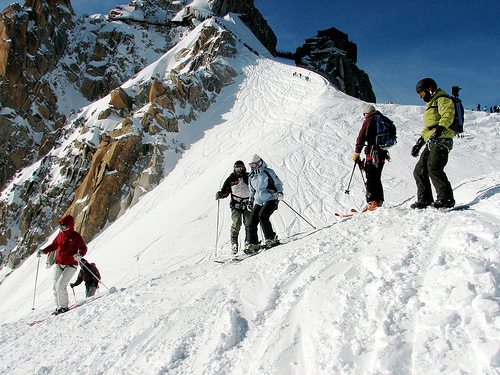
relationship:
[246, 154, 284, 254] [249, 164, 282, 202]
person wears jacket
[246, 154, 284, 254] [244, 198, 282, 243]
person wears pants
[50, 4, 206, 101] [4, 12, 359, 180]
snow on mountain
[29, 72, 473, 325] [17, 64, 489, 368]
people on hill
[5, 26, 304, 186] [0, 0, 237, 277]
snow on rocks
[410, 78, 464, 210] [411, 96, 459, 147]
man wears green jacket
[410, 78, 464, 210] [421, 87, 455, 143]
man wears green jacket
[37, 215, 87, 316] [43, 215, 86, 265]
people wears jacket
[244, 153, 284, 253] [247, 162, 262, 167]
person wears goggles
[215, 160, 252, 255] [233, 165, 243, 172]
man wears goggles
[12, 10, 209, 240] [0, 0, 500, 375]
snow on hill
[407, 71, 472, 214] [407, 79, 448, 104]
man wears helmet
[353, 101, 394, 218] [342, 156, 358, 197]
person holds pole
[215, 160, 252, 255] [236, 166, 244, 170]
man wearing goggles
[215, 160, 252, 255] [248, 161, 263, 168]
man wearing goggles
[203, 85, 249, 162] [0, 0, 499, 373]
track in snow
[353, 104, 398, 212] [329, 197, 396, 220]
person on skis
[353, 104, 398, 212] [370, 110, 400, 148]
person wearing backpack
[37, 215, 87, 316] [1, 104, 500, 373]
people skiing down hillside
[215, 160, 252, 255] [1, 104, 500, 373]
man skiing down hillside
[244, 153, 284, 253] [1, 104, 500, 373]
person skiing down hillside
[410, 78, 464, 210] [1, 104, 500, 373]
man skiing down hillside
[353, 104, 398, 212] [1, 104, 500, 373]
person skiing down hillside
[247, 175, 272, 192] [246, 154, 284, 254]
jacket worn by behind person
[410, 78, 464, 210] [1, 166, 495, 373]
man standing on hillside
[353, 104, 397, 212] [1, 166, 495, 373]
man standing on hillside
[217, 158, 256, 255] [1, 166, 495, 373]
man standing on hillside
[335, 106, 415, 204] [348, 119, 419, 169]
man wearing outfit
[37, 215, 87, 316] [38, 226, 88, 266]
people wearing jacket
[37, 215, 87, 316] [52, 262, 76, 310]
people wearing trousers